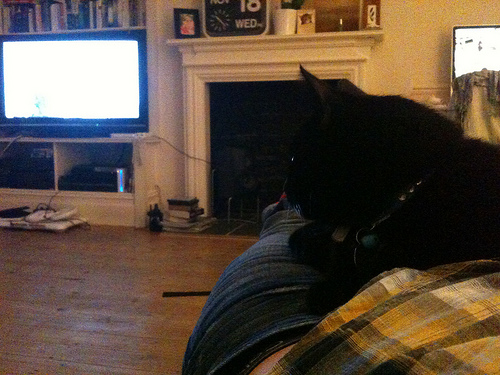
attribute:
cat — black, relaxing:
[273, 59, 499, 322]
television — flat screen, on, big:
[0, 21, 154, 147]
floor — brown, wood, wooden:
[0, 220, 266, 375]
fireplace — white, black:
[165, 27, 390, 228]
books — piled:
[155, 191, 217, 238]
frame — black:
[169, 7, 204, 41]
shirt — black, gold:
[234, 250, 498, 374]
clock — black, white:
[200, 0, 272, 40]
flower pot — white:
[271, 7, 298, 37]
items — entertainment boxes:
[0, 200, 96, 242]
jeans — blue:
[166, 191, 338, 375]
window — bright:
[453, 23, 499, 80]